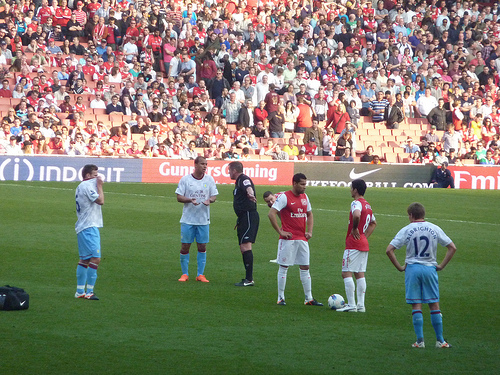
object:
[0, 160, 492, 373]
soccer game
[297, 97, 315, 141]
spectator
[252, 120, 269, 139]
spectator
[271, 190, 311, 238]
jersey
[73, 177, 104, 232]
jersey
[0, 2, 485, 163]
spectators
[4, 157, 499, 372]
game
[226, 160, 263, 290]
referee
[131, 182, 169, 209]
line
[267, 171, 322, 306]
player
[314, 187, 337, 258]
ground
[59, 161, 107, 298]
player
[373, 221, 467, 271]
jersey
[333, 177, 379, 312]
player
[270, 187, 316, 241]
shirt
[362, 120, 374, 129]
seat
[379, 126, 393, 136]
seat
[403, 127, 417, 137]
seat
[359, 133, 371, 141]
seat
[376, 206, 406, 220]
line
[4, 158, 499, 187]
sign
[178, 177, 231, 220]
jersey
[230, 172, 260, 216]
black shirt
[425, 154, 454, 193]
man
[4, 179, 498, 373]
grass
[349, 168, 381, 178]
nike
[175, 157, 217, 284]
man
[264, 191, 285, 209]
player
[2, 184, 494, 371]
field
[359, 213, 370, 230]
number 8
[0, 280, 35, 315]
bag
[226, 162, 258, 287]
official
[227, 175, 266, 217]
jersey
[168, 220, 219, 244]
shorts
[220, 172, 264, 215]
shirt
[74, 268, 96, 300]
sock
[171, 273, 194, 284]
shoe